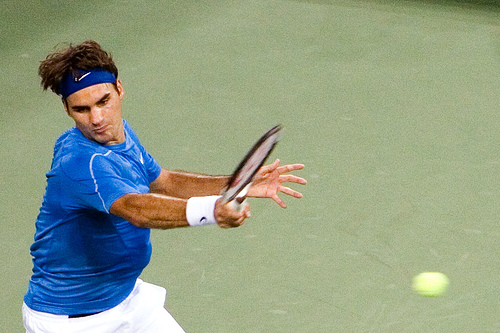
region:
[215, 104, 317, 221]
a tennis racket in a hand.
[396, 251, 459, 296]
a green tennis ball.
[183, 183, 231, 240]
a wrist guard.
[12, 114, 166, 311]
a blue t shirt.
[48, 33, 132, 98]
a dark blue head band.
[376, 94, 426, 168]
a section of a green tennis court.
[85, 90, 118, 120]
a man's left eye.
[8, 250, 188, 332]
a pair of white pants.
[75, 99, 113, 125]
a human nose.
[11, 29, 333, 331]
a man swinging a tennis racket at a ball.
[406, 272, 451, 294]
a small green tennis ball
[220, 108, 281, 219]
a black and white tennis racket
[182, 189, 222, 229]
a white wristband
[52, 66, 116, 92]
a blue headband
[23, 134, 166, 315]
a man's short sleeve blue shirt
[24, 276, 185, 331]
a man's white bottoms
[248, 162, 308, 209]
the hand of a man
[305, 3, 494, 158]
part of a tennis court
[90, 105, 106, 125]
the nose of a man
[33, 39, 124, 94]
brown hair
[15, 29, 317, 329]
Player is playing tennis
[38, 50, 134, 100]
Tennis player is wearing a head sweatband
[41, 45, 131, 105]
Sweatband is blue in color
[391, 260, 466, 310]
Tennis ball is in the air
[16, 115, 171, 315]
Man is wearing a blue shirt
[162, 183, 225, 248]
Man is wearing a white wristband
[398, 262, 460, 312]
Tennis ball is yellow in color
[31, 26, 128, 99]
Man has brown hair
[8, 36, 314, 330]
Man is in the foreground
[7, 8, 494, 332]
Background is light green in color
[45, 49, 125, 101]
man wearing a blue headband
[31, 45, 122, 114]
man with brown hair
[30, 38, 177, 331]
man wearing a blue shirt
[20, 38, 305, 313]
man holding a tennis racket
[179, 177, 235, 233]
white wristband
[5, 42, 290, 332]
man wearing white shorts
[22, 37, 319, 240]
man wearing a wristband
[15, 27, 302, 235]
man playing tennis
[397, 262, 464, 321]
small yellow tennis ball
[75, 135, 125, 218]
white stripe on blue shirt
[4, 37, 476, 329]
tennis player just hit ball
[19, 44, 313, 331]
male tennis player in action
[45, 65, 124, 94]
blue nike headband with white swoosh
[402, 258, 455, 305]
yellow tennis ball in flight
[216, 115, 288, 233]
tennis racquet held in right hand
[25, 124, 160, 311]
blue short-sleeved shirt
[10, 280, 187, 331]
white athletic shorts worn by tennis player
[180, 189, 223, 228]
wrist band worn on right wrist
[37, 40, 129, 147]
man making strange face